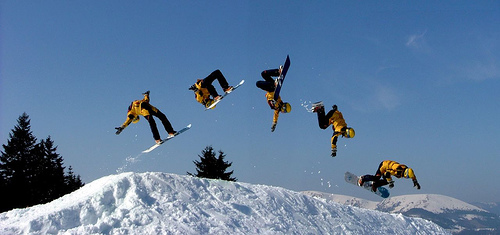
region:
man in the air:
[350, 152, 432, 197]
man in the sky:
[303, 88, 364, 153]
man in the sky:
[255, 52, 301, 132]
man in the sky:
[190, 53, 251, 121]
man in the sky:
[100, 82, 195, 154]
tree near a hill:
[190, 138, 242, 180]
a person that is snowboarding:
[107, 73, 189, 182]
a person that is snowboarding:
[177, 34, 236, 130]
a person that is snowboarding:
[307, 94, 365, 161]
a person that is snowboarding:
[355, 149, 415, 216]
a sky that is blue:
[19, 2, 489, 219]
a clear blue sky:
[42, 23, 499, 175]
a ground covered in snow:
[193, 187, 347, 231]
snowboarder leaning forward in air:
[340, 150, 420, 200]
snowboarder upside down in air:
[255, 45, 295, 130]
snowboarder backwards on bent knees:
[185, 60, 240, 110]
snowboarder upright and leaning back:
[110, 85, 190, 155]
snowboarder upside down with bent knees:
[307, 93, 355, 162]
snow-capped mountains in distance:
[298, 185, 493, 231]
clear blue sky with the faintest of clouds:
[9, 7, 494, 206]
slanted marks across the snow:
[60, 172, 282, 229]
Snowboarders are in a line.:
[105, 55, 427, 206]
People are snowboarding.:
[101, 59, 426, 199]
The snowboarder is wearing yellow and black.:
[101, 91, 192, 156]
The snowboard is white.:
[139, 122, 194, 153]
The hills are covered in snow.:
[10, 170, 498, 231]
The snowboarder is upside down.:
[255, 58, 303, 137]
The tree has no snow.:
[189, 144, 239, 187]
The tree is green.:
[191, 146, 236, 184]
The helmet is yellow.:
[403, 169, 416, 183]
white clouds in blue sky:
[391, 18, 422, 62]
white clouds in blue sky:
[382, 102, 433, 127]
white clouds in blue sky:
[31, 12, 61, 46]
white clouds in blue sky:
[85, 16, 127, 47]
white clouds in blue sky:
[388, 51, 460, 109]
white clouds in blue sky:
[447, 73, 491, 97]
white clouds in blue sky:
[400, 28, 451, 70]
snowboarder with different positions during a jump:
[109, 55, 424, 198]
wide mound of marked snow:
[9, 165, 446, 231]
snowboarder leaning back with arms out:
[112, 86, 189, 152]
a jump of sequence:
[89, 35, 454, 217]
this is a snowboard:
[132, 122, 202, 153]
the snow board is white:
[141, 119, 196, 156]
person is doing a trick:
[75, 57, 480, 228]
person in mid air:
[111, 47, 433, 204]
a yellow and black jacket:
[109, 90, 174, 129]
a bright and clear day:
[13, 5, 495, 231]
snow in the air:
[299, 151, 341, 197]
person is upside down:
[304, 92, 369, 172]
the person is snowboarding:
[60, 35, 462, 207]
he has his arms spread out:
[85, 57, 194, 166]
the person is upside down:
[247, 30, 302, 151]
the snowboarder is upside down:
[308, 80, 363, 172]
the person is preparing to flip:
[87, 63, 205, 177]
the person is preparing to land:
[340, 137, 447, 218]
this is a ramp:
[0, 161, 157, 222]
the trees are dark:
[10, 98, 101, 210]